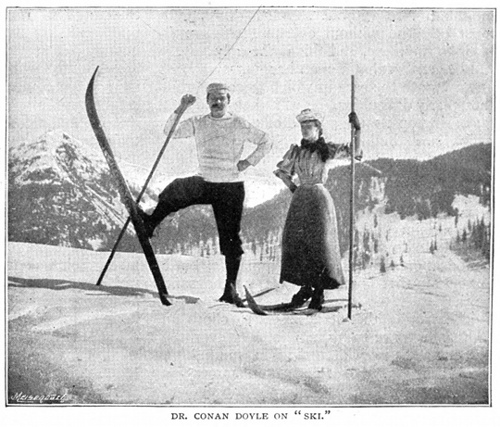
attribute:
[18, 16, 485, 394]
photo — black, white, ski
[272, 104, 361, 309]
woman — enjoying herself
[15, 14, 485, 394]
day — clear, sunny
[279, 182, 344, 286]
skirt — long 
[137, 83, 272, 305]
man — happy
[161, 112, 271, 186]
shirt — white 